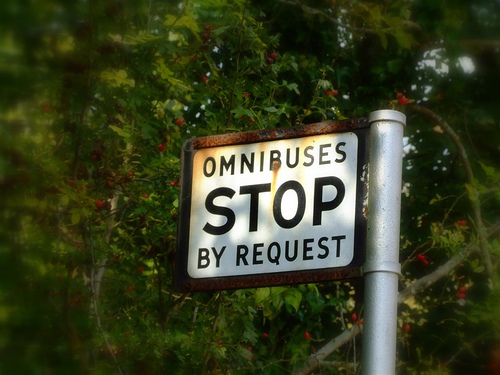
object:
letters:
[203, 157, 216, 178]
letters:
[285, 145, 315, 167]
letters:
[318, 141, 348, 164]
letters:
[272, 176, 346, 229]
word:
[195, 137, 347, 269]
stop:
[203, 175, 348, 236]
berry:
[303, 331, 311, 341]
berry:
[415, 253, 429, 265]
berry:
[175, 117, 185, 126]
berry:
[202, 75, 208, 84]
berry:
[204, 24, 211, 31]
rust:
[171, 115, 370, 294]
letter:
[259, 150, 265, 172]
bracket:
[360, 260, 403, 279]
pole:
[362, 109, 408, 375]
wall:
[361, 103, 418, 166]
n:
[240, 151, 255, 174]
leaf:
[0, 0, 499, 375]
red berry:
[458, 283, 468, 300]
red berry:
[95, 198, 106, 209]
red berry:
[157, 142, 165, 152]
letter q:
[266, 242, 281, 266]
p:
[313, 175, 346, 226]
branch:
[300, 103, 500, 375]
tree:
[0, 0, 500, 375]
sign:
[169, 113, 370, 296]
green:
[0, 0, 500, 375]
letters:
[235, 243, 263, 267]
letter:
[269, 149, 281, 172]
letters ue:
[283, 238, 315, 262]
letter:
[196, 247, 211, 269]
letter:
[211, 246, 227, 268]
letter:
[284, 239, 299, 261]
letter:
[302, 238, 314, 261]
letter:
[218, 154, 235, 176]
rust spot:
[173, 266, 366, 293]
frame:
[173, 114, 373, 293]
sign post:
[177, 105, 407, 375]